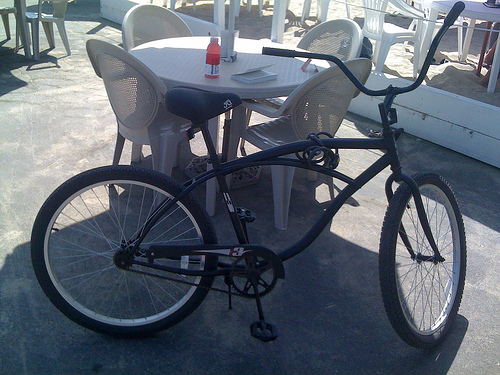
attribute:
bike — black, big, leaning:
[31, 1, 467, 352]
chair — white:
[225, 58, 373, 228]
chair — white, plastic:
[86, 38, 219, 206]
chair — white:
[361, 0, 424, 78]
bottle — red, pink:
[204, 37, 220, 79]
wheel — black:
[30, 164, 218, 338]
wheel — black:
[378, 170, 466, 350]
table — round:
[126, 36, 337, 191]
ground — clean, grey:
[1, 1, 500, 375]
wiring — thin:
[47, 183, 201, 320]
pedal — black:
[250, 321, 279, 343]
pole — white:
[271, 0, 287, 44]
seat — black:
[166, 85, 242, 125]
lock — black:
[296, 131, 339, 171]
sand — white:
[137, 1, 499, 107]